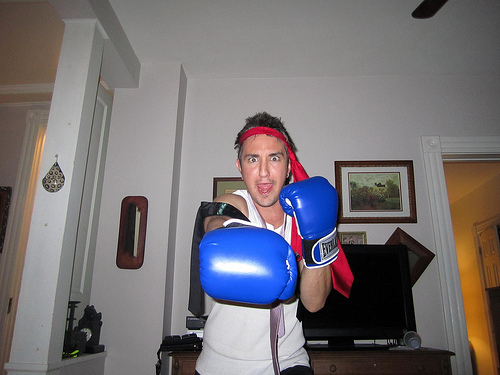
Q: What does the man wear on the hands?
A: Gloves.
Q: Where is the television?
A: Behind the man.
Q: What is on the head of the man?
A: A neck tie.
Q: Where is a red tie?
A: Around man's head.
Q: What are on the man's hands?
A: Boxing gloves.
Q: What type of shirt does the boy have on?
A: A tank top.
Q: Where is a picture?
A: On the wall over the TV.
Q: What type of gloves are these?
A: Boxing gloves.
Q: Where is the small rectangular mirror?
A: On wall behind boy.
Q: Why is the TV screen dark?
A: TV turned off.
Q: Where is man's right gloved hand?
A: In front of his body.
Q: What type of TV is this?
A: Flat screen TV.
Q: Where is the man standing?
A: In a room.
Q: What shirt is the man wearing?
A: A long white tank top.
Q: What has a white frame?
A: The doorway.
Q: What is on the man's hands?
A: Blue boxing gloves.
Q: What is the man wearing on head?
A: A red necktie.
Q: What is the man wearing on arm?
A: A black necktie.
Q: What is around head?
A: A red tie.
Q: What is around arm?
A: A black necktie.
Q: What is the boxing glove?
A: Blue, white, and black.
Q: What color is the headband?
A: Red.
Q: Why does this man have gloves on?
A: To box.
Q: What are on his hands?
A: Boxing gloves.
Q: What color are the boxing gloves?
A: Blue.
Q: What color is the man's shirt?
A: White.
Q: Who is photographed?
A: A man.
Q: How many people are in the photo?
A: One.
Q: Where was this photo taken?
A: At a house.